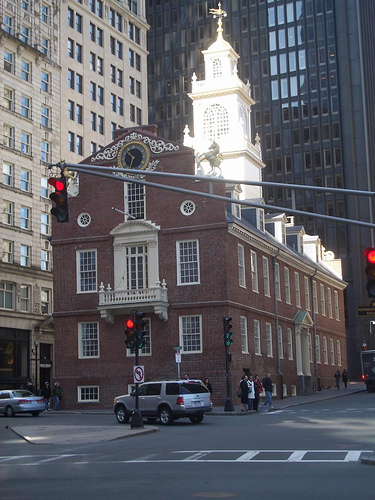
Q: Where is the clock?
A: At the top of the red brick building.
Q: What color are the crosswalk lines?
A: White.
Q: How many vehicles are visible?
A: Three.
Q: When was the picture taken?
A: Daytime.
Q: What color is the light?
A: Red.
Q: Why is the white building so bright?
A: Its in the sun.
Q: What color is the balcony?
A: White.